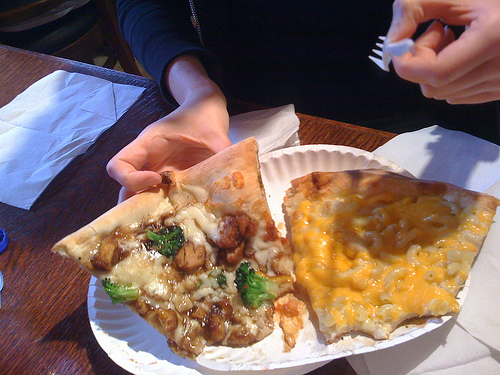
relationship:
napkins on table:
[211, 99, 496, 371] [8, 41, 496, 373]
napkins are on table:
[379, 128, 499, 188] [381, 132, 416, 156]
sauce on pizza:
[324, 245, 395, 268] [47, 134, 498, 360]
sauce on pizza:
[208, 314, 266, 342] [282, 170, 498, 344]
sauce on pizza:
[208, 314, 266, 342] [48, 139, 299, 350]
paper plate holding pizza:
[193, 143, 469, 372] [102, 161, 474, 342]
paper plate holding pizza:
[84, 260, 333, 373] [102, 161, 474, 342]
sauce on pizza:
[281, 187, 496, 329] [282, 170, 498, 344]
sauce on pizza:
[281, 187, 496, 329] [48, 139, 299, 350]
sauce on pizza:
[289, 192, 493, 332] [282, 170, 498, 344]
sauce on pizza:
[360, 303, 393, 338] [282, 170, 498, 344]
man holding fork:
[96, 2, 498, 276] [351, 31, 431, 74]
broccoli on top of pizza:
[144, 225, 185, 257] [50, 135, 309, 360]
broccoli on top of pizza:
[233, 260, 280, 307] [50, 135, 309, 360]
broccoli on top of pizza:
[99, 276, 141, 305] [50, 135, 309, 360]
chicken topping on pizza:
[90, 240, 123, 270] [50, 135, 309, 360]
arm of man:
[165, 64, 222, 98] [96, 2, 499, 206]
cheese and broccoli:
[168, 203, 225, 250] [231, 259, 272, 306]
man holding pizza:
[96, 2, 499, 206] [104, 147, 296, 339]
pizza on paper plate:
[48, 139, 299, 350] [193, 143, 469, 372]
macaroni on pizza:
[298, 205, 408, 294] [283, 167, 465, 300]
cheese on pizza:
[378, 254, 444, 306] [283, 167, 465, 300]